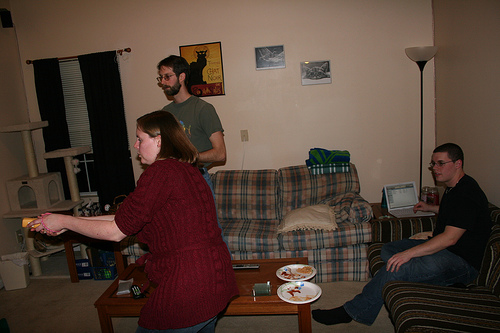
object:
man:
[309, 143, 491, 328]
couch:
[365, 198, 498, 330]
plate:
[275, 263, 323, 305]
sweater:
[115, 156, 243, 323]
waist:
[148, 234, 223, 261]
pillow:
[276, 202, 337, 234]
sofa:
[206, 163, 370, 284]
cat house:
[3, 120, 93, 217]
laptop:
[381, 182, 434, 221]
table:
[372, 206, 388, 217]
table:
[91, 252, 316, 332]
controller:
[20, 214, 45, 231]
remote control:
[231, 264, 262, 270]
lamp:
[402, 40, 441, 201]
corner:
[404, 42, 447, 207]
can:
[0, 249, 31, 291]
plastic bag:
[1, 248, 30, 267]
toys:
[77, 193, 103, 217]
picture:
[176, 40, 224, 97]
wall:
[0, 0, 500, 206]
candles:
[417, 181, 440, 205]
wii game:
[21, 217, 64, 226]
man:
[153, 56, 226, 189]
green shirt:
[162, 95, 224, 162]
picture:
[299, 56, 331, 86]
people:
[22, 50, 488, 332]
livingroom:
[0, 2, 500, 332]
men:
[23, 56, 492, 329]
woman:
[33, 111, 236, 330]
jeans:
[340, 238, 486, 327]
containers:
[420, 186, 439, 203]